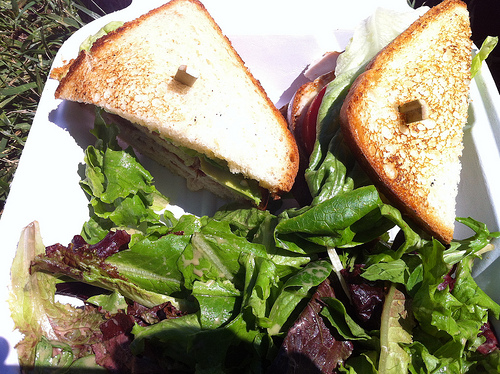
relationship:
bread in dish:
[48, 2, 488, 252] [10, 12, 478, 372]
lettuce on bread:
[299, 89, 445, 278] [341, 5, 479, 242]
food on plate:
[44, 21, 477, 233] [4, 1, 497, 369]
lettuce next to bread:
[9, 107, 497, 370] [338, 0, 472, 246]